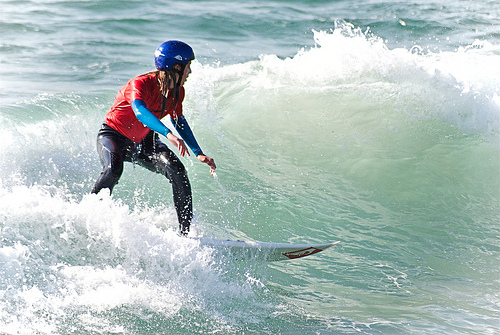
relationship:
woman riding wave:
[49, 41, 294, 240] [1, 19, 498, 332]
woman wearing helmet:
[49, 41, 294, 240] [156, 40, 196, 70]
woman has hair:
[49, 41, 294, 240] [156, 60, 179, 101]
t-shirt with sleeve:
[108, 67, 185, 140] [133, 102, 173, 144]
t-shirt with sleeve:
[108, 67, 185, 140] [172, 105, 202, 159]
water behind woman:
[0, 1, 492, 106] [49, 41, 294, 240]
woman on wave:
[49, 41, 294, 240] [1, 19, 498, 332]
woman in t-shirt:
[49, 41, 294, 240] [108, 67, 185, 140]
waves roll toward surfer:
[333, 118, 440, 158] [87, 30, 211, 265]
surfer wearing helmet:
[31, 37, 330, 282] [150, 35, 195, 75]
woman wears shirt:
[49, 41, 294, 240] [83, 60, 228, 155]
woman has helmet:
[49, 41, 294, 240] [152, 41, 194, 69]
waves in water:
[27, 180, 140, 263] [6, 137, 91, 332]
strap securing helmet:
[163, 64, 187, 88] [151, 35, 192, 70]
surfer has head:
[31, 37, 330, 282] [144, 31, 198, 92]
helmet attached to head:
[151, 35, 192, 70] [144, 31, 198, 92]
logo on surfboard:
[279, 246, 322, 260] [192, 228, 349, 267]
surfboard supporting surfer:
[192, 228, 349, 267] [31, 37, 330, 282]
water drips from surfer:
[212, 181, 266, 251] [31, 37, 330, 282]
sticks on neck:
[160, 65, 187, 107] [152, 66, 189, 102]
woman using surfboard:
[49, 41, 294, 240] [134, 210, 344, 285]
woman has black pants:
[49, 41, 294, 240] [93, 116, 210, 236]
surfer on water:
[31, 37, 330, 282] [1, 19, 498, 332]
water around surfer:
[1, 19, 498, 332] [31, 37, 330, 282]